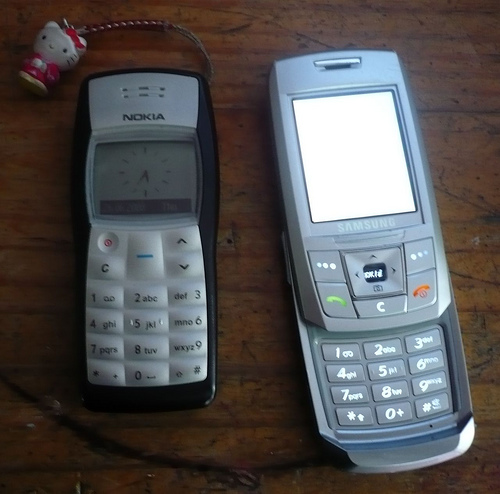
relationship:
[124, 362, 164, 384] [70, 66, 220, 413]
"0" button on phone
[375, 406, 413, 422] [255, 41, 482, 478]
"0" button on cell phone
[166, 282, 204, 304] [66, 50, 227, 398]
number on phone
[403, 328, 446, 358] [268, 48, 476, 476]
number 3 on cell phone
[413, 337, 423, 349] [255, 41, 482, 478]
number 3 on cell phone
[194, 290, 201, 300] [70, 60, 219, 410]
number on phone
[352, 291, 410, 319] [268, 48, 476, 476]
letter c on cell phone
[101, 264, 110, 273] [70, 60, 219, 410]
letter c on phone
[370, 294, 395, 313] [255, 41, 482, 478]
letter on cell phone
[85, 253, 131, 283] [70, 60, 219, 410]
letter c on phone